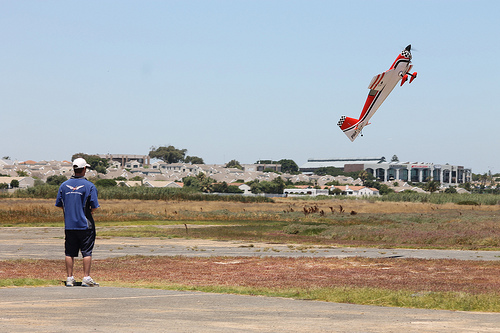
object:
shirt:
[53, 174, 100, 229]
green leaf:
[209, 187, 222, 194]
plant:
[180, 171, 240, 194]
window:
[409, 167, 420, 182]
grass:
[0, 253, 499, 315]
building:
[280, 186, 331, 198]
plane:
[335, 44, 417, 142]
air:
[164, 16, 236, 83]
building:
[342, 154, 473, 187]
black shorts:
[63, 224, 99, 258]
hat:
[70, 157, 93, 171]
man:
[54, 157, 100, 288]